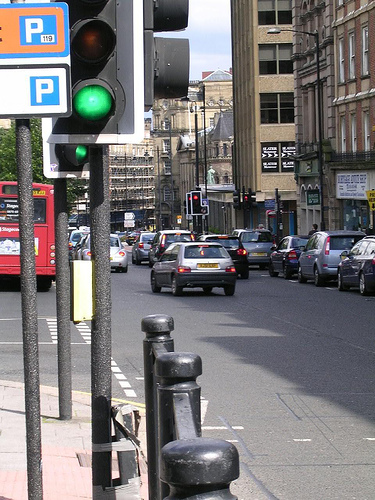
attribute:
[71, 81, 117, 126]
traffic light — green, black, white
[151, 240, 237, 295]
car — light colored, grey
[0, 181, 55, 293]
bus — red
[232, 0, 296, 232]
building — tall, sandy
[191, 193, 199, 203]
stop light — red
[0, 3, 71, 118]
street sign — blue, white, orange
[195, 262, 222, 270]
tag — yellow, black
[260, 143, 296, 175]
sign — black, white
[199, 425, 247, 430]
marking — white, painted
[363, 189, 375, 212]
road sign — yellow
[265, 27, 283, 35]
street lamp — overhead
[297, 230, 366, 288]
car — silver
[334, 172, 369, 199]
sign — white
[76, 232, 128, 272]
car — silver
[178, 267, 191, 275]
light — red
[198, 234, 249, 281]
car — black